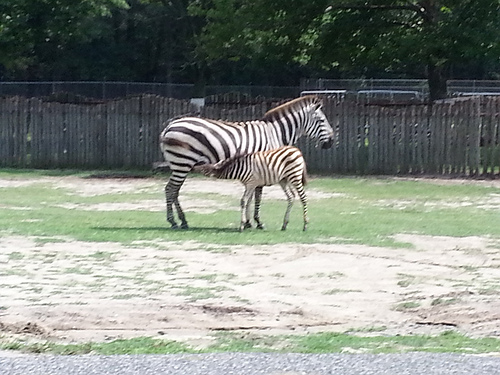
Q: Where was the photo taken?
A: It was taken at the park.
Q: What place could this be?
A: It is a park.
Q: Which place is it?
A: It is a park.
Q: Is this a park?
A: Yes, it is a park.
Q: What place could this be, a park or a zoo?
A: It is a park.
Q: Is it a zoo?
A: No, it is a park.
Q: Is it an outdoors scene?
A: Yes, it is outdoors.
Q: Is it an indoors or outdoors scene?
A: It is outdoors.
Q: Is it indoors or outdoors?
A: It is outdoors.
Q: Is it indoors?
A: No, it is outdoors.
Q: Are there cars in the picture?
A: No, there are no cars.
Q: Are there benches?
A: No, there are no benches.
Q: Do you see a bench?
A: No, there are no benches.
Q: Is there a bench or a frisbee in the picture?
A: No, there are no benches or frisbees.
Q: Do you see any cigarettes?
A: No, there are no cigarettes.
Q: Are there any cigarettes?
A: No, there are no cigarettes.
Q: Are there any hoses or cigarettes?
A: No, there are no cigarettes or hoses.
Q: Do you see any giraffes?
A: No, there are no giraffes.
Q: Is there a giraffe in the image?
A: No, there are no giraffes.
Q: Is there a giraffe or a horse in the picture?
A: No, there are no giraffes or horses.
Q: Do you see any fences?
A: Yes, there is a fence.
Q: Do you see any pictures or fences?
A: Yes, there is a fence.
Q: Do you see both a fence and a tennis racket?
A: No, there is a fence but no rackets.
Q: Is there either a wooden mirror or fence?
A: Yes, there is a wood fence.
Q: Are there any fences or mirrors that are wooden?
A: Yes, the fence is wooden.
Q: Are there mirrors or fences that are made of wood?
A: Yes, the fence is made of wood.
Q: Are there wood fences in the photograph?
A: Yes, there is a wood fence.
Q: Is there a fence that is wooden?
A: Yes, there is a fence that is wooden.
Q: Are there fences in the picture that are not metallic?
A: Yes, there is a wooden fence.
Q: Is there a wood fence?
A: Yes, there is a fence that is made of wood.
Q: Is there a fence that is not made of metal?
A: Yes, there is a fence that is made of wood.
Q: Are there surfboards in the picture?
A: No, there are no surfboards.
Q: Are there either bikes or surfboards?
A: No, there are no surfboards or bikes.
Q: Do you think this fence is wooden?
A: Yes, the fence is wooden.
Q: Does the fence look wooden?
A: Yes, the fence is wooden.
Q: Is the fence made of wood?
A: Yes, the fence is made of wood.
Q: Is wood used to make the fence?
A: Yes, the fence is made of wood.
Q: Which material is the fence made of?
A: The fence is made of wood.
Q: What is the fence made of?
A: The fence is made of wood.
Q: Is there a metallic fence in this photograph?
A: No, there is a fence but it is wooden.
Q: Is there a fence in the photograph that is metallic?
A: No, there is a fence but it is wooden.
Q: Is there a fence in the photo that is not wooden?
A: No, there is a fence but it is wooden.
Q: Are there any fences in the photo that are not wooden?
A: No, there is a fence but it is wooden.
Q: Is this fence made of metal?
A: No, the fence is made of wood.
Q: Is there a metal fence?
A: No, there is a fence but it is made of wood.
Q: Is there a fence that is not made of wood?
A: No, there is a fence but it is made of wood.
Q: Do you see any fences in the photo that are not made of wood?
A: No, there is a fence but it is made of wood.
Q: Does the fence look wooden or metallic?
A: The fence is wooden.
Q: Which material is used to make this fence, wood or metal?
A: The fence is made of wood.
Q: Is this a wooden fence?
A: Yes, this is a wooden fence.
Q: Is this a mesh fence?
A: No, this is a wooden fence.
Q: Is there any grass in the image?
A: Yes, there is grass.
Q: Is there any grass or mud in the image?
A: Yes, there is grass.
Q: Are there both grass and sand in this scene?
A: Yes, there are both grass and sand.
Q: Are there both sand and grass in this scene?
A: Yes, there are both grass and sand.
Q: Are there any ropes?
A: No, there are no ropes.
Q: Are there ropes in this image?
A: No, there are no ropes.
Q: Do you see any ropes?
A: No, there are no ropes.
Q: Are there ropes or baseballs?
A: No, there are no ropes or baseballs.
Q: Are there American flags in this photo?
A: No, there are no American flags.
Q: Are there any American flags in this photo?
A: No, there are no American flags.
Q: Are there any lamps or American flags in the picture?
A: No, there are no American flags or lamps.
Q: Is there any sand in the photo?
A: Yes, there is sand.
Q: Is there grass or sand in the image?
A: Yes, there is sand.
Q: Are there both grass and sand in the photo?
A: Yes, there are both sand and grass.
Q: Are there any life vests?
A: No, there are no life vests.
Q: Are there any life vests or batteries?
A: No, there are no life vests or batteries.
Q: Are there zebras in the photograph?
A: Yes, there is a zebra.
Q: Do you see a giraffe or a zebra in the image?
A: Yes, there is a zebra.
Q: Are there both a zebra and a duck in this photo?
A: No, there is a zebra but no ducks.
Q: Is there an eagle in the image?
A: No, there are no eagles.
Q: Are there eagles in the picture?
A: No, there are no eagles.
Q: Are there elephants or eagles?
A: No, there are no eagles or elephants.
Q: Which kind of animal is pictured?
A: The animal is a zebra.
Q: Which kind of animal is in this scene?
A: The animal is a zebra.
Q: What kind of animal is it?
A: The animal is a zebra.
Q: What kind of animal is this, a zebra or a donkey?
A: This is a zebra.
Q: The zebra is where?
A: The zebra is in the grass.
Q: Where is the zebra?
A: The zebra is in the grass.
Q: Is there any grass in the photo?
A: Yes, there is grass.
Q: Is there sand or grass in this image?
A: Yes, there is grass.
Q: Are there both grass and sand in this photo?
A: Yes, there are both grass and sand.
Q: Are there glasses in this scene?
A: No, there are no glasses.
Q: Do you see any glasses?
A: No, there are no glasses.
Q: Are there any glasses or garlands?
A: No, there are no glasses or garlands.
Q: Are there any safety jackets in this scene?
A: No, there are no safety jackets.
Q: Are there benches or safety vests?
A: No, there are no safety vests or benches.